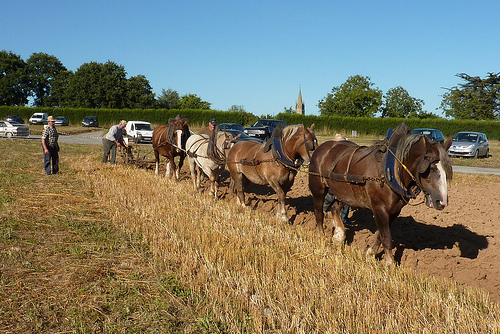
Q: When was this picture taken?
A: During the day.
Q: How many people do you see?
A: 2.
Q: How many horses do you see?
A: 4.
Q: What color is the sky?
A: Blue.